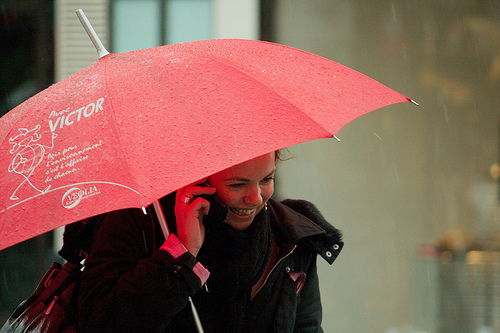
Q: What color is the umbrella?
A: Red.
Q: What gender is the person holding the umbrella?
A: Female.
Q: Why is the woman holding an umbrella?
A: It is raining.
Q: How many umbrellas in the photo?
A: One.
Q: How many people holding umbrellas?
A: One.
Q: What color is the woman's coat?
A: Black.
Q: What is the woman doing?
A: Talking on phone.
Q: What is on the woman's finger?
A: Ring.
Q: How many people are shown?
A: One.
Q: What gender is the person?
A: Female.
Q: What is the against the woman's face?
A: Cell phone.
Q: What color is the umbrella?
A: Pink.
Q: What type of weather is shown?
A: Rainy.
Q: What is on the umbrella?
A: Rain water.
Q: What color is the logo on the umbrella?
A: White.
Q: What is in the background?
A: Building.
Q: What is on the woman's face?
A: Smile.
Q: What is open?
A: Umbrella.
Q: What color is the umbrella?
A: Red.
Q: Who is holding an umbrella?
A: A woman.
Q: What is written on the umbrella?
A: "VICTOR".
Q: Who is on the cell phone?
A: The woman.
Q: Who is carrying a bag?
A: The woman.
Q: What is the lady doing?
A: Talking on her cellphone.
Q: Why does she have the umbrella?
A: It's raining out.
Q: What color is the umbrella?
A: Red.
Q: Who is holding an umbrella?
A: A lady.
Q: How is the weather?
A: It's raining.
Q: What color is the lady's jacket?
A: Black.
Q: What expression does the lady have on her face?
A: Smiles.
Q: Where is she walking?
A: On a sidewalk in front of storefront windows.